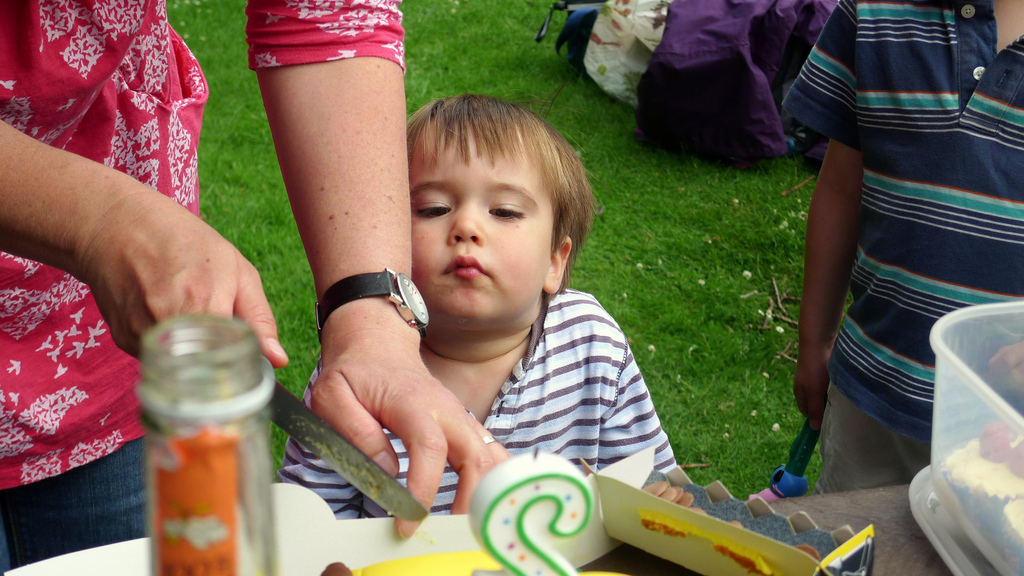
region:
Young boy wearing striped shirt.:
[267, 79, 695, 501]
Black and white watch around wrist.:
[304, 253, 440, 339]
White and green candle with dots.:
[471, 439, 599, 573]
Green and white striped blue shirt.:
[779, 6, 1020, 440]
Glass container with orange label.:
[133, 307, 274, 573]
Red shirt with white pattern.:
[4, 3, 415, 498]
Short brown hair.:
[409, 89, 596, 290]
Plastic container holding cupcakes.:
[925, 300, 1021, 573]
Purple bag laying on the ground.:
[637, 0, 840, 163]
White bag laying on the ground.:
[582, 0, 665, 106]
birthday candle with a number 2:
[473, 449, 594, 570]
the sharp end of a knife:
[274, 377, 430, 521]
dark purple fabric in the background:
[637, 7, 830, 164]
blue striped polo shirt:
[787, 4, 1018, 438]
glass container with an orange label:
[138, 313, 278, 564]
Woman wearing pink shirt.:
[2, 0, 430, 513]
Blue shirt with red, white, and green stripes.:
[802, 2, 1021, 399]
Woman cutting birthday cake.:
[252, 261, 611, 565]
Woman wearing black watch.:
[172, 192, 480, 471]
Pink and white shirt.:
[2, 2, 328, 262]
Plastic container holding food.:
[925, 295, 1020, 534]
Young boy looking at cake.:
[410, 91, 614, 572]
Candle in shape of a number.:
[460, 437, 604, 573]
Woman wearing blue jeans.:
[2, 2, 158, 572]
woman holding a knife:
[6, 29, 534, 562]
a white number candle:
[440, 410, 614, 563]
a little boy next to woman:
[300, 88, 665, 487]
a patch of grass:
[628, 193, 762, 358]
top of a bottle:
[127, 306, 327, 466]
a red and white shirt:
[18, 0, 415, 493]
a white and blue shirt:
[490, 312, 665, 481]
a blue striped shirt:
[753, 4, 1022, 396]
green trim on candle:
[455, 445, 595, 569]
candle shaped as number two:
[457, 429, 607, 570]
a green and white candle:
[469, 441, 594, 569]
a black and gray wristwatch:
[301, 256, 428, 332]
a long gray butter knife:
[253, 375, 446, 519]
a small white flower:
[734, 263, 760, 290]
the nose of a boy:
[449, 208, 485, 244]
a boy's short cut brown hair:
[400, 91, 597, 298]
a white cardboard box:
[583, 464, 803, 573]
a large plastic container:
[925, 310, 1021, 558]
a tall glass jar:
[134, 315, 297, 572]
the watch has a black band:
[311, 268, 430, 342]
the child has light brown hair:
[286, 95, 691, 514]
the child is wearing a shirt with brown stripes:
[276, 92, 685, 517]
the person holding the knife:
[1, 0, 511, 536]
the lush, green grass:
[160, 0, 853, 501]